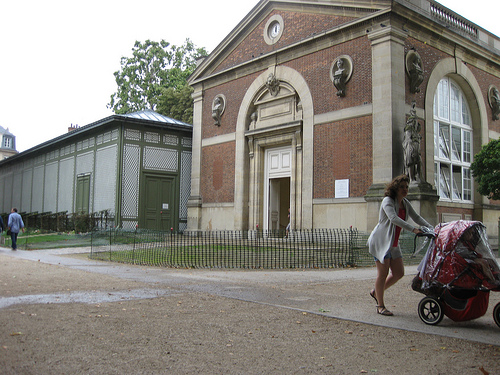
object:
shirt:
[395, 205, 406, 249]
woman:
[370, 172, 439, 317]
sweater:
[367, 195, 433, 264]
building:
[181, 1, 498, 249]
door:
[74, 174, 91, 230]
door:
[137, 166, 179, 234]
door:
[265, 180, 281, 239]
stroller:
[409, 220, 499, 329]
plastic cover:
[414, 218, 499, 291]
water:
[4, 296, 46, 304]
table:
[262, 132, 297, 242]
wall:
[214, 145, 235, 174]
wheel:
[418, 296, 444, 325]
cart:
[412, 220, 500, 326]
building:
[0, 106, 192, 239]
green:
[144, 172, 177, 225]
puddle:
[3, 290, 153, 305]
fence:
[87, 224, 369, 273]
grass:
[193, 239, 230, 258]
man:
[4, 207, 26, 249]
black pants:
[11, 232, 18, 250]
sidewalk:
[0, 244, 498, 371]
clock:
[267, 20, 280, 40]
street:
[0, 241, 497, 373]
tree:
[104, 36, 208, 124]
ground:
[0, 227, 499, 375]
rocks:
[5, 253, 495, 373]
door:
[267, 176, 290, 238]